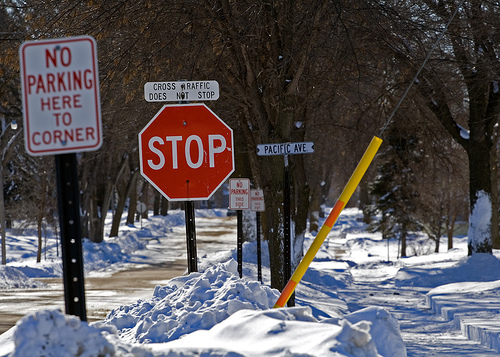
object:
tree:
[1, 10, 152, 248]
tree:
[126, 0, 394, 299]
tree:
[404, 126, 470, 254]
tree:
[368, 99, 441, 258]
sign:
[250, 188, 266, 212]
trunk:
[429, 64, 498, 255]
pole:
[273, 132, 385, 311]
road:
[0, 209, 238, 339]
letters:
[18, 36, 101, 156]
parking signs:
[145, 80, 217, 101]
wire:
[265, 1, 467, 311]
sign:
[227, 175, 250, 210]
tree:
[357, 2, 499, 260]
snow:
[463, 186, 495, 252]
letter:
[139, 102, 235, 201]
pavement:
[0, 201, 243, 355]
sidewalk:
[343, 224, 498, 357]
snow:
[0, 189, 500, 357]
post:
[228, 179, 248, 279]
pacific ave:
[258, 142, 312, 156]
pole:
[52, 150, 86, 322]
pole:
[183, 199, 198, 273]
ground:
[0, 204, 500, 354]